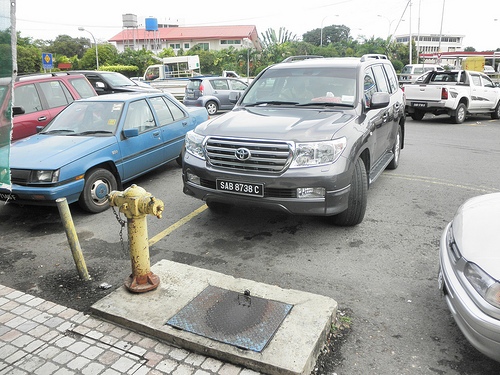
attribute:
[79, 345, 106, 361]
tile — square, white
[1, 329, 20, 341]
tile — square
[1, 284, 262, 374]
tiles — white, pinkish white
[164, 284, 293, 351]
manhole cover — square, blue, metal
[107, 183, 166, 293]
fire hydrant — yellow, metal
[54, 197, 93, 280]
stop pole — faded, yellow, concrete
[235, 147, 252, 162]
logo — stylized, silver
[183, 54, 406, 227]
suv — dark grey, toyota, black, parked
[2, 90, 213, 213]
car — blue, parked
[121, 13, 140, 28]
water tank — grey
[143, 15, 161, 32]
water tank — blue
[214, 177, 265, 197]
license plate — black, white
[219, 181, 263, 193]
writing — white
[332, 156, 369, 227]
wheel — turned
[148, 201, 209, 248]
line — yellow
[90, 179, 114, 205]
hubcap — blue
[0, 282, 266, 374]
sidewalk — brick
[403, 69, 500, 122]
truck — white, parked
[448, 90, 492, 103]
marks — black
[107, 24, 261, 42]
roof — red